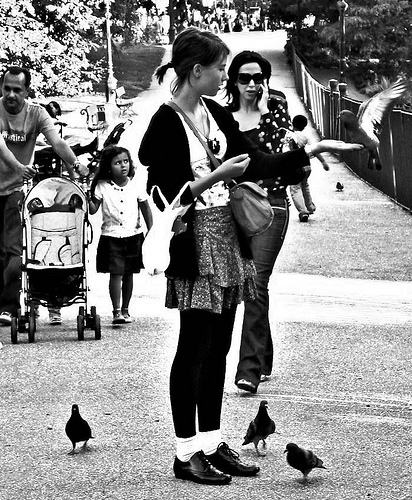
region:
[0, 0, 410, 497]
a black and white picture of a park scene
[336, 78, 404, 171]
a pigeon landing on a girls hand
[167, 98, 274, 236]
the girl has a shoulder strap purse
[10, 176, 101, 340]
a man pushing a stroller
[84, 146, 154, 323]
a little girl walking next to the stroller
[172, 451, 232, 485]
a girl wearing black lace shoes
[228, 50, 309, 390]
a lady on a cell pone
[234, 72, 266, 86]
a lady is wearing dark sunglasses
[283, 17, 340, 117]
a fence runs along the park walkway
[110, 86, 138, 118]
a park bench next to the street light post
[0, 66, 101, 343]
man pushing baby carriage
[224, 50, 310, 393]
young woman wearing sunglasses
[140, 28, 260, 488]
young woman carrying plastic bag on right arm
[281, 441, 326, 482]
pigeon on ground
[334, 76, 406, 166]
flying pigeon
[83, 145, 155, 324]
little girl wearing white shirt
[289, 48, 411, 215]
wrought iron fence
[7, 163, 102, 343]
empty baby carriage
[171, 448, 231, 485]
woman's right black shoe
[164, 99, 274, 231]
woman's leather shoulder bag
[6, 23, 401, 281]
The picture is in black and white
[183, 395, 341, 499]
The birds are on the ground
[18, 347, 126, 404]
The ground is gray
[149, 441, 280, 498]
The woman has black shoes on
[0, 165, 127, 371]
The stroller is empty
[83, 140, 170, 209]
The girl is looking away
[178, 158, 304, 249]
The woman has a purse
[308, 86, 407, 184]
The bird is eating out of her hand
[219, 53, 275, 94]
The woman has sunglasses on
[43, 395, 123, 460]
The bird is dark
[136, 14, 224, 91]
girl has dark hair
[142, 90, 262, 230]
girl has dark shirt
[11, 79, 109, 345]
man pushing a pram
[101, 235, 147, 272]
girl has dark skirt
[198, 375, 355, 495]
dark colored birds on ground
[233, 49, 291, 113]
woman is wearing sunglasses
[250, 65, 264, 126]
woman holds cell phone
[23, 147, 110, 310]
pram is light colored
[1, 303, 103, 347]
pram has dark colored wheels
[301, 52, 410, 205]
fence next to people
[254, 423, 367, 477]
pigeon on the ground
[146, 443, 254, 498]
woman's shoes on the ground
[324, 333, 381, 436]
pavement the woman is on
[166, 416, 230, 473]
woman's socks on feet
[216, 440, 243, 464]
shoe laces on shoes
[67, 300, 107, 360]
wheels of baby carrage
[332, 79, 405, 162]
pigeon flying in the air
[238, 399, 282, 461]
pigeon walking in the street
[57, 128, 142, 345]
little girl walking next to stroller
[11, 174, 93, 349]
baby stroller on the street